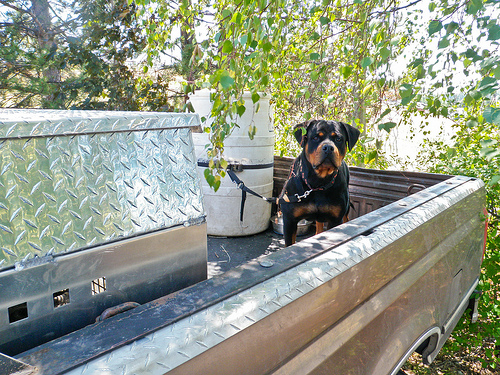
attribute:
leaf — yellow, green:
[250, 90, 262, 105]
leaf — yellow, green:
[428, 15, 443, 39]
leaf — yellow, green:
[376, 118, 402, 135]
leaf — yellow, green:
[260, 35, 275, 57]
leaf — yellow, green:
[361, 147, 380, 168]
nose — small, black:
[312, 142, 342, 172]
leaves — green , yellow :
[223, 11, 232, 21]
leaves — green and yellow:
[186, 16, 475, 136]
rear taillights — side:
[479, 202, 488, 260]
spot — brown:
[316, 132, 325, 140]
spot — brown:
[327, 129, 338, 139]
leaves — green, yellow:
[97, 0, 142, 44]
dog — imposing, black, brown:
[275, 112, 363, 247]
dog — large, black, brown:
[279, 120, 359, 246]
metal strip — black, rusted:
[24, 175, 479, 369]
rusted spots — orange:
[147, 289, 222, 311]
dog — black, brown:
[282, 121, 354, 231]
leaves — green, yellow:
[133, 0, 376, 112]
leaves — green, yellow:
[281, 35, 451, 150]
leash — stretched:
[225, 163, 279, 219]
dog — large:
[281, 93, 384, 240]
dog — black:
[275, 118, 355, 240]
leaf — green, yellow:
[429, 20, 441, 35]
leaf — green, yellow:
[464, 56, 474, 65]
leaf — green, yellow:
[361, 54, 371, 66]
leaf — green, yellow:
[481, 102, 498, 130]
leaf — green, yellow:
[378, 120, 398, 133]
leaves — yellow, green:
[202, 164, 221, 193]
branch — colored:
[141, 15, 462, 146]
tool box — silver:
[1, 95, 233, 307]